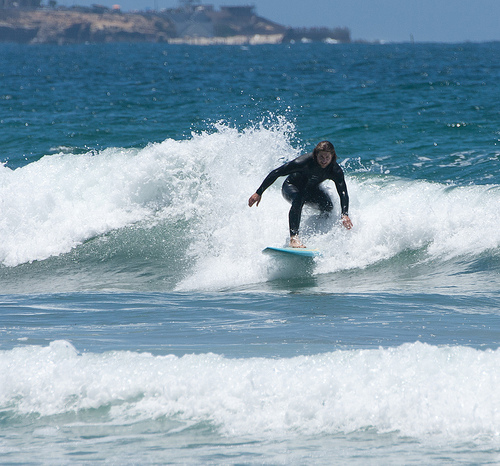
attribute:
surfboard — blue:
[262, 243, 320, 259]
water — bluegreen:
[52, 46, 432, 128]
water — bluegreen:
[6, 46, 493, 152]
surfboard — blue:
[253, 238, 324, 268]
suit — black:
[256, 153, 349, 237]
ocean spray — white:
[207, 89, 306, 223]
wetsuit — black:
[257, 157, 349, 237]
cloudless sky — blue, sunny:
[9, 0, 499, 46]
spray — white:
[201, 102, 306, 219]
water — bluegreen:
[81, 53, 411, 181]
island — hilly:
[63, 5, 373, 49]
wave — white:
[205, 127, 268, 176]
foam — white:
[8, 340, 497, 445]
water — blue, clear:
[246, 47, 343, 82]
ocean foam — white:
[74, 346, 419, 419]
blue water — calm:
[346, 56, 442, 108]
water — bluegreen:
[33, 53, 441, 140]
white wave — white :
[3, 110, 498, 286]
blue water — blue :
[1, 35, 498, 175]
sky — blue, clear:
[38, 0, 498, 44]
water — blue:
[45, 270, 465, 362]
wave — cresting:
[82, 142, 311, 322]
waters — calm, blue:
[72, 158, 220, 310]